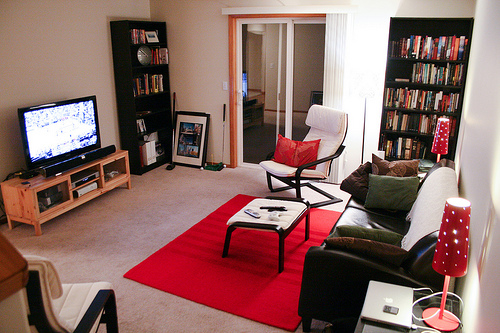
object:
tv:
[15, 93, 118, 180]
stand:
[0, 145, 133, 237]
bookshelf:
[106, 17, 178, 178]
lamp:
[418, 196, 473, 332]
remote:
[240, 206, 264, 218]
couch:
[291, 151, 465, 332]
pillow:
[362, 171, 418, 218]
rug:
[120, 192, 350, 332]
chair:
[256, 101, 351, 212]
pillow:
[270, 133, 322, 170]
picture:
[168, 109, 211, 172]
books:
[158, 74, 165, 95]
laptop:
[356, 278, 414, 329]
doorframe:
[223, 12, 345, 187]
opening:
[101, 156, 131, 186]